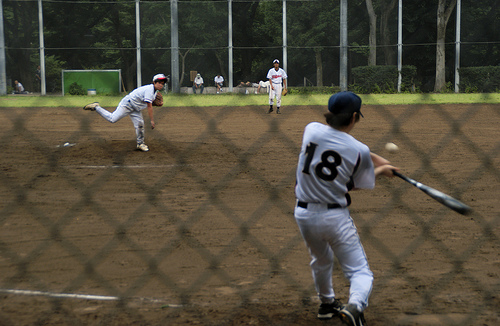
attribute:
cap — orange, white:
[147, 71, 171, 90]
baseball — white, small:
[379, 128, 414, 174]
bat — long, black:
[372, 150, 474, 223]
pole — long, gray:
[165, 0, 185, 92]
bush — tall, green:
[346, 55, 427, 101]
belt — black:
[317, 200, 348, 215]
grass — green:
[183, 85, 272, 111]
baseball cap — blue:
[314, 84, 374, 125]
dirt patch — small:
[199, 231, 266, 280]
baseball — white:
[385, 140, 401, 152]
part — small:
[82, 293, 101, 297]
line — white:
[3, 288, 194, 309]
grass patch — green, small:
[453, 94, 492, 104]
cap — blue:
[323, 90, 364, 117]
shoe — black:
[341, 300, 369, 323]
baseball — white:
[381, 139, 400, 154]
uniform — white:
[292, 122, 376, 307]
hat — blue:
[327, 89, 367, 118]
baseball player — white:
[83, 71, 170, 149]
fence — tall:
[1, 40, 496, 91]